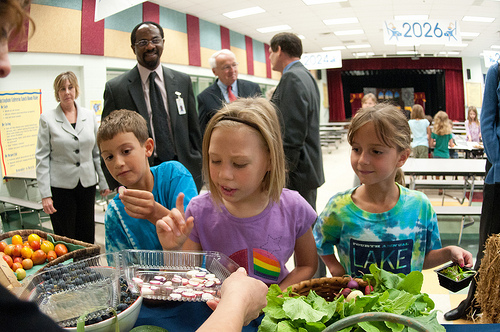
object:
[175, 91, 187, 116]
badge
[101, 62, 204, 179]
suit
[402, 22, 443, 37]
2026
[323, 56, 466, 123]
curtains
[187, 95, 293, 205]
head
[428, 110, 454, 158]
kid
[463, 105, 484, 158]
kid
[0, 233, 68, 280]
sample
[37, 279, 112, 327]
sample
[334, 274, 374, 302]
sample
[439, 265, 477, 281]
sample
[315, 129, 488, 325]
ground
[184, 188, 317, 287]
purple shirt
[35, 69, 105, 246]
woman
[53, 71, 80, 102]
hair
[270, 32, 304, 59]
hair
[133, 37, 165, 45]
glasses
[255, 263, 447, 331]
greens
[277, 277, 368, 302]
basket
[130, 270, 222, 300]
radish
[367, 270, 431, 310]
spinach leaves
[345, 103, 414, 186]
hair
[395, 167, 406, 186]
ponytail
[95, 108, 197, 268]
boy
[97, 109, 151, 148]
hair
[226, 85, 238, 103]
tie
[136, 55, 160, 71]
neck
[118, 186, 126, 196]
radish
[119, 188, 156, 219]
hand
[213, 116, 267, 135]
headband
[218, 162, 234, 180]
nose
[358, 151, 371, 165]
nose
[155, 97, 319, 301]
girl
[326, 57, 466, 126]
stage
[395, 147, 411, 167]
ear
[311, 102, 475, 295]
girl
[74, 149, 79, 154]
buttons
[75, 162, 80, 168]
buttons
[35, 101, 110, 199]
shirt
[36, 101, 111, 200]
jacket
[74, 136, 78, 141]
buttons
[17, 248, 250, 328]
tray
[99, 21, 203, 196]
man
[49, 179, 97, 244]
skirt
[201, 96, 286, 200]
hair